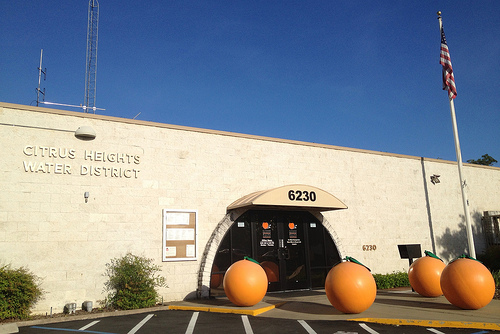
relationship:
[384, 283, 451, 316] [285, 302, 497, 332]
shadow casted on ground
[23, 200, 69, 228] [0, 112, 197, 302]
paint on wall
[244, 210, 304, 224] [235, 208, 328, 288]
frame on door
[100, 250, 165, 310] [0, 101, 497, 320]
bush front of building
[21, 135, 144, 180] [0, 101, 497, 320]
words on building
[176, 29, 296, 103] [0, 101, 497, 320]
sky above building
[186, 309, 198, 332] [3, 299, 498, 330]
line on ground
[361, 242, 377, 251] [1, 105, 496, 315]
number on wall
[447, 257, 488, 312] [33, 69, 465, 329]
orange in front of building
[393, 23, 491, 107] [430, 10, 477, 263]
flag on flag pole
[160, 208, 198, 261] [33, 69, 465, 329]
announcement board on building